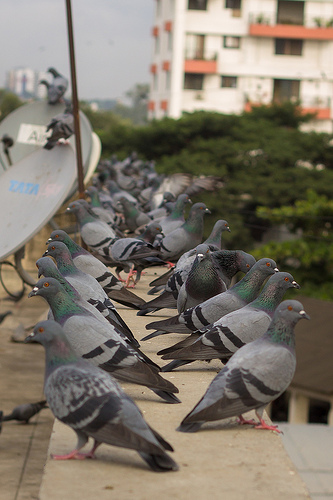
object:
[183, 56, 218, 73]
balcony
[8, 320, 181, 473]
bird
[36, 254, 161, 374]
bird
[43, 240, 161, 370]
bird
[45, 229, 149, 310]
bird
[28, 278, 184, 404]
bird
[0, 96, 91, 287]
satellite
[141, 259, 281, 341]
pigeon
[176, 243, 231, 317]
pigeon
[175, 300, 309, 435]
bird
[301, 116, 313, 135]
ground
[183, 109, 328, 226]
trees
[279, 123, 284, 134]
ground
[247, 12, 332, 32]
plants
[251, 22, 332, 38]
balcony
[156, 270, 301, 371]
bird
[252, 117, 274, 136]
ground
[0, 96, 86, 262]
satellite dish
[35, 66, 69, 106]
pigeon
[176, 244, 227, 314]
bird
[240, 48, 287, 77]
ground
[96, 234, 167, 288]
bird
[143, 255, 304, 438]
three pigeons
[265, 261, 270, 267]
red eyes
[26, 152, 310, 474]
bird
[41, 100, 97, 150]
bird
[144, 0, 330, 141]
building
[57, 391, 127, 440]
tripes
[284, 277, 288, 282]
eye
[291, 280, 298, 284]
beak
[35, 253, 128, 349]
pigeon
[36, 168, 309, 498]
ledge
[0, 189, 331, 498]
building